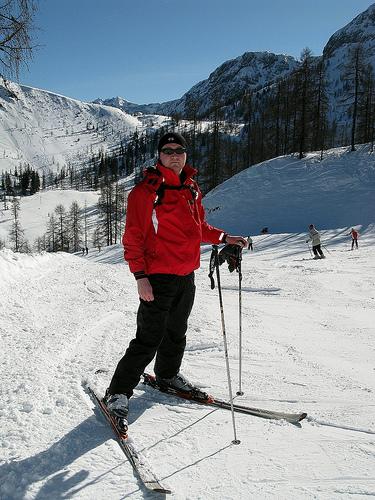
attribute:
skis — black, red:
[85, 374, 315, 492]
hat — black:
[151, 119, 195, 168]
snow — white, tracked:
[257, 263, 348, 306]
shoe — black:
[155, 371, 202, 391]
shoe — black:
[105, 385, 129, 423]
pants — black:
[107, 270, 197, 395]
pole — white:
[207, 244, 240, 443]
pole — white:
[236, 243, 244, 395]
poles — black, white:
[205, 236, 251, 450]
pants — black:
[94, 263, 218, 429]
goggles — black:
[124, 138, 208, 156]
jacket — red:
[122, 168, 220, 275]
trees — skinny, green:
[3, 158, 39, 196]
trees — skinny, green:
[36, 198, 91, 253]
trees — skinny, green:
[73, 145, 124, 191]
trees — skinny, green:
[204, 84, 321, 189]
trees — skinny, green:
[135, 117, 156, 162]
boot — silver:
[154, 370, 200, 394]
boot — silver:
[102, 385, 130, 424]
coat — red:
[121, 161, 226, 281]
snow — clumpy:
[3, 325, 89, 425]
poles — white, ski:
[204, 267, 270, 470]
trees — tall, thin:
[62, 189, 116, 267]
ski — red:
[85, 379, 170, 498]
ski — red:
[141, 370, 307, 426]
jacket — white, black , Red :
[117, 160, 228, 281]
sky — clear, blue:
[29, 10, 343, 130]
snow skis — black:
[85, 357, 309, 497]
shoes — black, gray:
[103, 373, 198, 418]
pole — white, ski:
[213, 250, 283, 410]